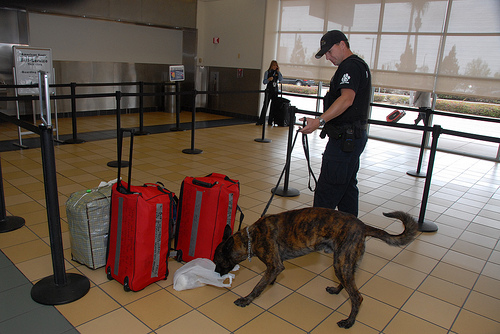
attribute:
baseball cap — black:
[313, 27, 347, 59]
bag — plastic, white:
[172, 256, 241, 296]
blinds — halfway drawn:
[271, 5, 497, 110]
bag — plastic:
[176, 252, 239, 293]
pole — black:
[39, 122, 68, 285]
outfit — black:
[324, 66, 376, 214]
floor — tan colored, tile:
[1, 108, 498, 331]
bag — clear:
[65, 175, 122, 269]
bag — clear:
[103, 126, 175, 291]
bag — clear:
[168, 256, 238, 291]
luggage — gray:
[68, 186, 117, 269]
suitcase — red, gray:
[176, 147, 290, 289]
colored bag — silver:
[75, 174, 132, 232]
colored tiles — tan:
[429, 254, 465, 312]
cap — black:
[312, 25, 350, 62]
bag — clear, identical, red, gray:
[173, 170, 240, 266]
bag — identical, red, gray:
[103, 178, 176, 291]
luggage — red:
[176, 169, 238, 269]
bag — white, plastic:
[173, 257, 236, 290]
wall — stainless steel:
[18, 1, 263, 121]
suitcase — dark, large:
[267, 77, 294, 124]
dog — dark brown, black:
[208, 207, 418, 328]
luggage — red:
[102, 185, 174, 290]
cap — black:
[313, 32, 342, 54]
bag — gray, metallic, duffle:
[95, 152, 214, 308]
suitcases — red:
[65, 125, 244, 290]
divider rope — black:
[4, 74, 498, 198]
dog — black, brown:
[216, 214, 391, 301]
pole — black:
[17, 123, 96, 313]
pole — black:
[409, 125, 451, 246]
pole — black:
[266, 104, 306, 196]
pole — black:
[179, 85, 210, 153]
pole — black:
[100, 90, 142, 173]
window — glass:
[270, 0, 499, 125]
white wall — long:
[27, 11, 182, 64]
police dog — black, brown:
[208, 203, 426, 321]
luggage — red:
[102, 174, 178, 294]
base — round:
[28, 271, 90, 307]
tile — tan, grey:
[391, 246, 440, 277]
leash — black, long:
[258, 127, 318, 220]